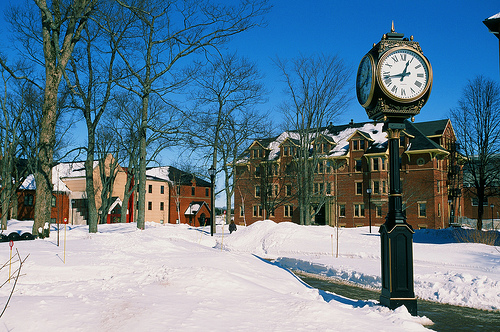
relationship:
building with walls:
[51, 160, 219, 232] [292, 141, 449, 228]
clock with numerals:
[374, 45, 432, 104] [380, 49, 429, 92]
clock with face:
[374, 45, 432, 104] [388, 61, 408, 86]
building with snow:
[230, 117, 462, 232] [270, 124, 385, 155]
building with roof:
[132, 165, 214, 227] [148, 166, 211, 189]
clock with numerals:
[364, 34, 439, 114] [398, 82, 411, 98]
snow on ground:
[242, 262, 312, 324] [88, 207, 332, 324]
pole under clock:
[374, 119, 424, 322] [362, 28, 431, 125]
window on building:
[142, 181, 153, 198] [49, 154, 216, 228]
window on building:
[157, 197, 167, 211] [49, 154, 216, 228]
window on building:
[145, 196, 155, 214] [49, 154, 216, 228]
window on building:
[159, 181, 166, 195] [49, 154, 216, 228]